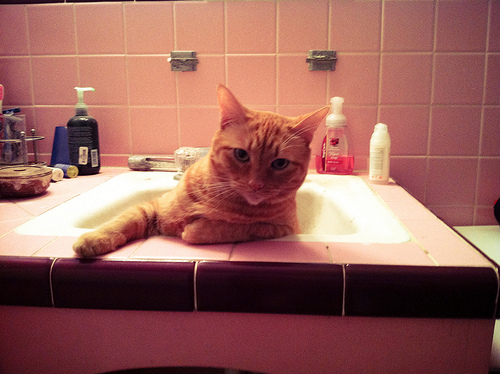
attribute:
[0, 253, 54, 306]
tile — dark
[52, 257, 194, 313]
tile — dark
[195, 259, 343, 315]
tile — dark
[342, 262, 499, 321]
tile — dark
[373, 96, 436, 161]
tile — pink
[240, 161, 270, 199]
nose — cat's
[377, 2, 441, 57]
tile — pink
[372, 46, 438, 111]
tile — pink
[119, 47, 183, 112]
tile — pink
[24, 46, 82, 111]
tile — pink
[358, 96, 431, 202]
soap — white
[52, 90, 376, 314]
cat — sitting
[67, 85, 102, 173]
dispenser — black, soap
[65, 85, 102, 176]
bottle — black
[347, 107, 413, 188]
bottle — white, plastic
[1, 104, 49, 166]
toothbrush holder — silver-plated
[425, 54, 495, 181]
tile — pink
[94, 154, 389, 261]
sink — white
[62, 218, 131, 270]
paw — cat's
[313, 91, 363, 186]
soap dispenser — pink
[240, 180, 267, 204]
nose — little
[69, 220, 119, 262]
paw — Cat's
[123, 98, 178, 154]
tile — pink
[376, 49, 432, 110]
tile — pink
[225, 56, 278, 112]
tile — pink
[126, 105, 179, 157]
tile — pink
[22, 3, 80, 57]
tile — pink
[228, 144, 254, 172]
eye — green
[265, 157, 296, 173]
eye — green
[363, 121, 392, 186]
bottle — small